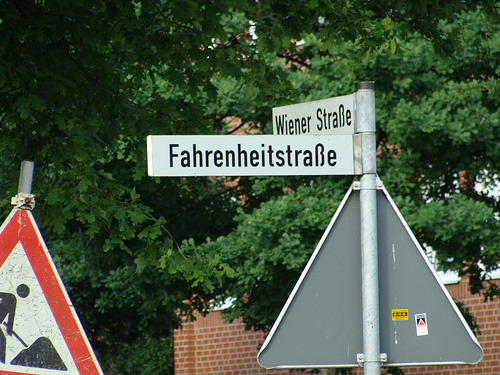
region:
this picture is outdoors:
[21, 33, 451, 359]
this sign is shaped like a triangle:
[285, 188, 484, 373]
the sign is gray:
[301, 183, 497, 373]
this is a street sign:
[133, 130, 365, 221]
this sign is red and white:
[5, 205, 85, 371]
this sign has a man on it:
[0, 260, 55, 342]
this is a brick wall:
[184, 310, 248, 367]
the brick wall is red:
[189, 329, 253, 371]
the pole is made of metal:
[310, 235, 467, 372]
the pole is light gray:
[349, 241, 389, 321]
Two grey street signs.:
[134, 80, 406, 185]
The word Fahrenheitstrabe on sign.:
[153, 135, 350, 173]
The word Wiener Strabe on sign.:
[267, 95, 359, 133]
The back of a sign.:
[255, 175, 490, 370]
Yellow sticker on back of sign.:
[387, 303, 410, 325]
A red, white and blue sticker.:
[412, 310, 429, 340]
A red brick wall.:
[169, 274, 499, 369]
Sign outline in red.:
[1, 193, 103, 373]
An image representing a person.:
[3, 275, 39, 372]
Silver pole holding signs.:
[345, 114, 401, 373]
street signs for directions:
[70, 74, 441, 363]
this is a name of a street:
[133, 128, 363, 201]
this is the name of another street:
[247, 98, 370, 145]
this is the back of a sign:
[251, 164, 498, 370]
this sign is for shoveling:
[2, 149, 114, 374]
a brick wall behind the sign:
[142, 263, 454, 373]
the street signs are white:
[122, 89, 387, 183]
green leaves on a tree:
[62, 87, 154, 277]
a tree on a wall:
[432, 142, 489, 289]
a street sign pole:
[338, 84, 418, 362]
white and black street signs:
[119, 69, 384, 194]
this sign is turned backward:
[251, 170, 452, 374]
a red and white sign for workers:
[9, 149, 127, 373]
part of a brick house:
[165, 292, 259, 374]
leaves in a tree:
[78, 202, 282, 301]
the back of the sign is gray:
[256, 209, 458, 359]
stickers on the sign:
[386, 299, 448, 342]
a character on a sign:
[3, 277, 34, 351]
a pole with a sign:
[346, 79, 392, 374]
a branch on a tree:
[444, 144, 495, 234]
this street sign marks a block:
[140, 129, 372, 187]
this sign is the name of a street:
[255, 93, 388, 133]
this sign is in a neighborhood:
[140, 74, 412, 210]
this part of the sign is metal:
[350, 86, 403, 186]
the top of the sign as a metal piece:
[9, 158, 63, 221]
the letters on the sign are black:
[162, 137, 333, 166]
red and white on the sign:
[16, 219, 71, 351]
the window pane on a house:
[418, 177, 499, 294]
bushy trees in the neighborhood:
[31, 45, 458, 272]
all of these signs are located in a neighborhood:
[8, 68, 430, 374]